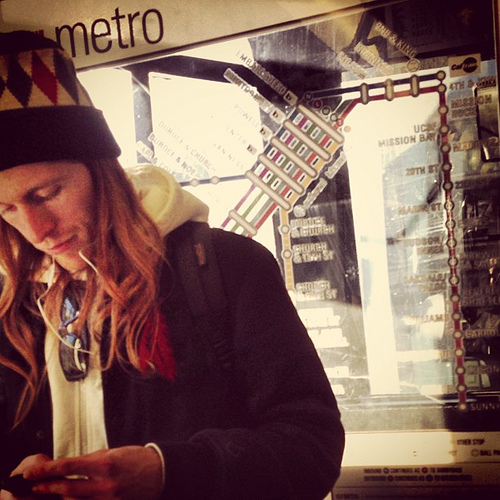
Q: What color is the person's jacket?
A: Black.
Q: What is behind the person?
A: Metro map.